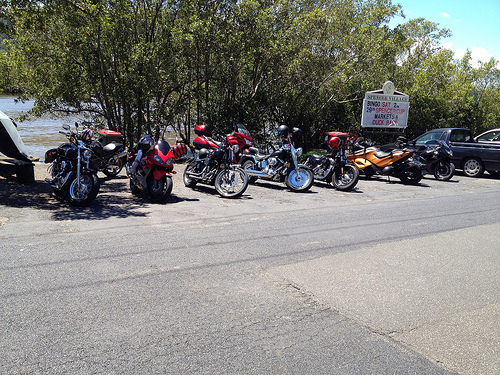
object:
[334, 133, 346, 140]
handlebar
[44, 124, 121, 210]
motorcycles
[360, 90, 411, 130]
sign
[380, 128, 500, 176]
truck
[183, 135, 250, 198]
motorcycle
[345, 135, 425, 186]
motorcycle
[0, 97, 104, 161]
water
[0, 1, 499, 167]
trees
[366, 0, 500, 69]
sky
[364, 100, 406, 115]
saturday at 2pm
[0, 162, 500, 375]
pavement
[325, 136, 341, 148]
helmet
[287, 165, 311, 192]
wheel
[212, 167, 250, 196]
black tire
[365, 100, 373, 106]
black letters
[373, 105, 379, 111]
letters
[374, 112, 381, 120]
blue letters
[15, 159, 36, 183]
container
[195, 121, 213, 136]
red container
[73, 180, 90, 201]
hubcap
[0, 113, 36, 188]
tent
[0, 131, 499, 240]
parking lot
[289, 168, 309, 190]
hubcap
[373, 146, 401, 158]
black sit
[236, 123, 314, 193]
motorcycle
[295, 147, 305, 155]
headlight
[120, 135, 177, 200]
motorcycle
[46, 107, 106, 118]
bow